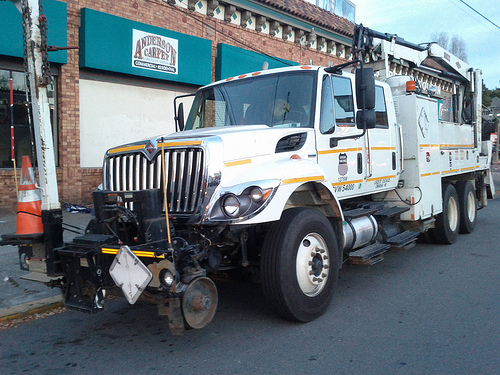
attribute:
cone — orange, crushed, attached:
[14, 156, 43, 234]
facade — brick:
[2, 1, 369, 208]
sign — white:
[131, 25, 180, 77]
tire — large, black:
[264, 207, 338, 324]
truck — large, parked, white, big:
[91, 47, 489, 323]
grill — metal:
[102, 145, 204, 224]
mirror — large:
[352, 59, 376, 125]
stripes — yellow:
[229, 143, 487, 179]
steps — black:
[373, 205, 425, 254]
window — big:
[0, 59, 76, 170]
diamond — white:
[109, 243, 151, 305]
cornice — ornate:
[182, 1, 359, 40]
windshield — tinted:
[178, 66, 321, 128]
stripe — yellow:
[102, 138, 201, 159]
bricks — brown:
[0, 0, 361, 214]